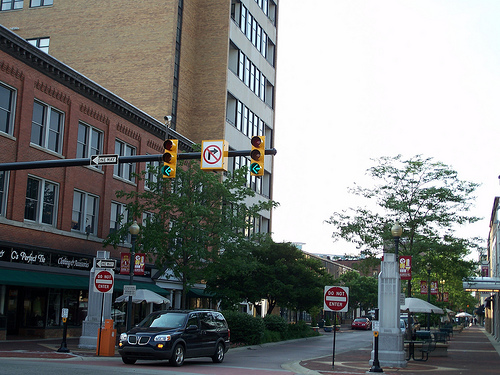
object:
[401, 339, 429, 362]
table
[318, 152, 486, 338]
green tree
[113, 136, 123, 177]
window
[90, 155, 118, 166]
sign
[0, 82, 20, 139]
window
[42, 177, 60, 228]
window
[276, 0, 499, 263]
sky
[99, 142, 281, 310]
tree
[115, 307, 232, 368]
mini van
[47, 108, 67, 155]
glass window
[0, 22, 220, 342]
building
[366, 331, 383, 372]
post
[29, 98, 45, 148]
glass window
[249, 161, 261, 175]
arrow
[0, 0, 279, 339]
brown building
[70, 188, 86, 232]
window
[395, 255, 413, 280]
sign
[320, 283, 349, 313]
sign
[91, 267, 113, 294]
sign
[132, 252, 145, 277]
sign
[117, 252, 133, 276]
sign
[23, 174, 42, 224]
window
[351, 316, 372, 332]
car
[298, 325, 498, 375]
sidewalk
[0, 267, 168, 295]
green canopy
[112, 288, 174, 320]
umbrella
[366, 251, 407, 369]
statue